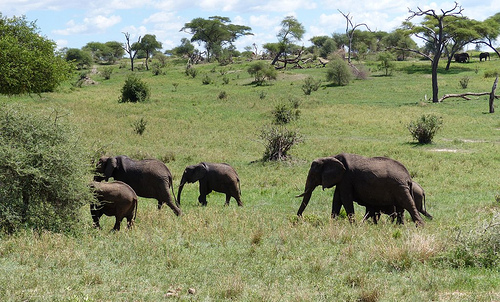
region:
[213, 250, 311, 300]
the grass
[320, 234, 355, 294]
the grass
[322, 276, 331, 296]
the grass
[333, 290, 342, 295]
the grass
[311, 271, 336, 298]
the grass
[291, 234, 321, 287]
the grass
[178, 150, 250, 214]
grey baby elephant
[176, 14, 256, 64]
tall tree in the distance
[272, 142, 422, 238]
big grey elephant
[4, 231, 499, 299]
yellow green grass in the foreground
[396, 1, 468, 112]
bare branched black tree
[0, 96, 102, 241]
light green scrubby bush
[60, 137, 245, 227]
group of three grey elephants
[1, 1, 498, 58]
bright blue cloudy sky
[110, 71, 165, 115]
dark green bush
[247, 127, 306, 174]
mostly brown dead bush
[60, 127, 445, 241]
the elephants are walking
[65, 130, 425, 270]
the elephants are gray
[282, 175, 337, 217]
the elephant has tusk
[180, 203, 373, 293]
the grass on the ground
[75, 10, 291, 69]
the sky has clouds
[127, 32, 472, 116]
trees in the distance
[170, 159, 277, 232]
a small elephant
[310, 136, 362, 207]
the ears are wide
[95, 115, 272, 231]
elephants walking to the right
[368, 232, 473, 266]
the grass is dry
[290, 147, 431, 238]
large gray elephant walking through green grassy field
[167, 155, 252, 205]
young gray elephant walking through green grassy field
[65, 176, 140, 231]
young gray elephant walking through green grassy field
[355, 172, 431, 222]
young gray elephant walking through green grassy field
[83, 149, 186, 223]
gray adult elephant walking through green grassy field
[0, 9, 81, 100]
large green bush next to open grassy field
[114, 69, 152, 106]
small green bush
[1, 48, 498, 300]
large green grassy field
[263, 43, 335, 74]
tree that has fallen over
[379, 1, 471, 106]
dark gray leafless tree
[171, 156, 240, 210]
a small grey elephant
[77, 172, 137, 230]
a small grey elephant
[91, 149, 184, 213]
a large grey elephant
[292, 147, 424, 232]
a large grey elephant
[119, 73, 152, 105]
a green bush in distance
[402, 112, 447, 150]
a green bush in distance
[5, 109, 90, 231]
a green tree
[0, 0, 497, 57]
a cloudy blue sky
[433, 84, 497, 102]
a fallen tree branch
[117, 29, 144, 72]
a bare tree